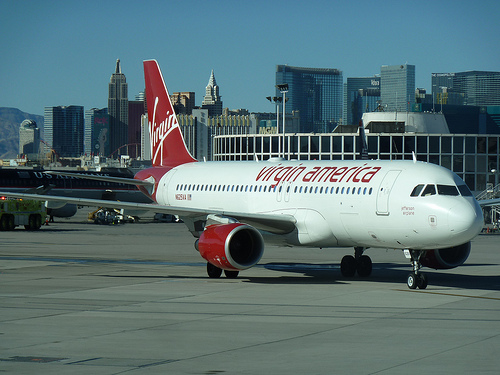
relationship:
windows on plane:
[238, 136, 413, 161] [6, 50, 494, 297]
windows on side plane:
[173, 180, 378, 195] [6, 50, 494, 297]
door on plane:
[371, 159, 426, 241] [18, 26, 490, 333]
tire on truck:
[28, 219, 42, 229] [4, 196, 48, 231]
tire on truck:
[1, 215, 13, 230] [4, 196, 48, 231]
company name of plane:
[256, 161, 381, 186] [6, 50, 494, 297]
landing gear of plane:
[340, 251, 375, 278] [80, 51, 489, 290]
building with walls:
[206, 129, 496, 197] [194, 132, 496, 167]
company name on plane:
[256, 162, 382, 188] [6, 50, 494, 297]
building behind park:
[102, 53, 134, 163] [5, 54, 490, 295]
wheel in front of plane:
[404, 268, 433, 292] [6, 50, 494, 297]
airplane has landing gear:
[0, 57, 485, 290] [192, 255, 367, 284]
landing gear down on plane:
[206, 243, 432, 301] [80, 51, 489, 290]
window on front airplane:
[411, 180, 423, 195] [13, 57, 497, 299]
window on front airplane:
[421, 184, 437, 198] [13, 57, 497, 299]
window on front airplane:
[437, 179, 458, 199] [13, 57, 497, 299]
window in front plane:
[420, 182, 438, 199] [6, 50, 494, 297]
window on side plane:
[292, 178, 300, 196] [6, 50, 494, 297]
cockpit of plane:
[411, 182, 477, 216] [6, 50, 494, 297]